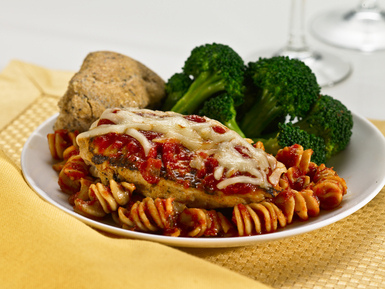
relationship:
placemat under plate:
[17, 208, 94, 266] [345, 147, 384, 192]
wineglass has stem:
[276, 0, 370, 80] [287, 5, 311, 34]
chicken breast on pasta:
[121, 157, 197, 197] [114, 192, 184, 232]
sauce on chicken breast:
[156, 128, 188, 161] [121, 157, 197, 197]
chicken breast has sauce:
[121, 157, 197, 197] [156, 128, 188, 161]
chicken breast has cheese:
[121, 157, 197, 197] [139, 112, 158, 131]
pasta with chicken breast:
[114, 192, 184, 232] [121, 157, 197, 197]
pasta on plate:
[114, 192, 184, 232] [345, 147, 384, 192]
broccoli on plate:
[191, 46, 312, 136] [345, 147, 384, 192]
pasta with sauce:
[114, 192, 184, 232] [156, 128, 188, 161]